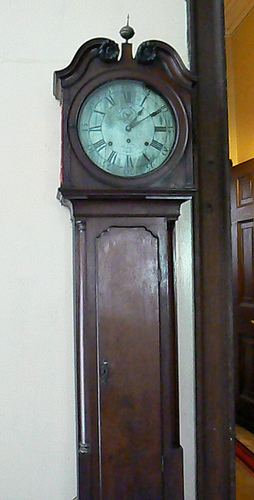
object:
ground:
[213, 79, 227, 96]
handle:
[100, 360, 107, 384]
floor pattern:
[233, 420, 253, 499]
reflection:
[136, 244, 190, 294]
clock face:
[74, 75, 185, 180]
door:
[231, 158, 253, 432]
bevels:
[236, 175, 252, 205]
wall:
[4, 46, 50, 267]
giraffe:
[222, 1, 231, 15]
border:
[227, 2, 249, 34]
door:
[76, 215, 184, 499]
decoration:
[98, 40, 118, 61]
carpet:
[235, 436, 253, 472]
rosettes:
[132, 39, 159, 62]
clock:
[52, 16, 200, 500]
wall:
[222, 0, 252, 166]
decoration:
[116, 22, 134, 41]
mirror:
[226, 301, 245, 466]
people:
[237, 368, 240, 373]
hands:
[126, 107, 160, 130]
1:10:
[136, 88, 165, 134]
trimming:
[222, 1, 244, 35]